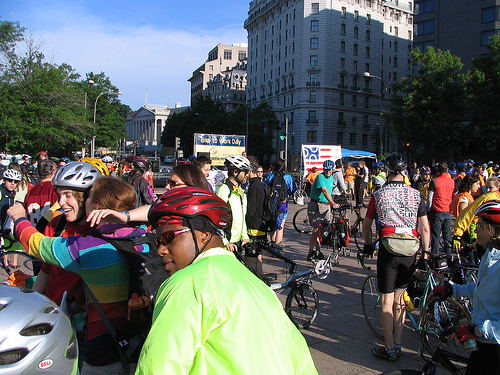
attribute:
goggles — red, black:
[145, 226, 202, 246]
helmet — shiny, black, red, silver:
[150, 188, 231, 229]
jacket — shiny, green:
[155, 307, 298, 373]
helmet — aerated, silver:
[40, 165, 96, 189]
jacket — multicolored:
[70, 216, 128, 298]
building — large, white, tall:
[243, 0, 382, 139]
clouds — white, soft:
[85, 32, 167, 81]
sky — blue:
[115, 1, 200, 34]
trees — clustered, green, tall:
[1, 80, 103, 147]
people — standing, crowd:
[213, 134, 452, 261]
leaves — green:
[39, 139, 75, 153]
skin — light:
[384, 174, 408, 181]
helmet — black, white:
[388, 153, 408, 168]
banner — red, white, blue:
[294, 138, 341, 173]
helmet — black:
[373, 154, 404, 169]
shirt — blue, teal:
[308, 178, 350, 203]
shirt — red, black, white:
[384, 181, 421, 232]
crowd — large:
[6, 136, 296, 278]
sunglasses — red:
[155, 227, 182, 247]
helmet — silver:
[225, 155, 253, 172]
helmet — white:
[3, 168, 22, 181]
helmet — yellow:
[75, 153, 108, 175]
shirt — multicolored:
[78, 231, 136, 330]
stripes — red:
[76, 261, 120, 296]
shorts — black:
[373, 247, 419, 291]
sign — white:
[303, 141, 337, 180]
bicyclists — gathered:
[1, 168, 480, 297]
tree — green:
[64, 75, 104, 151]